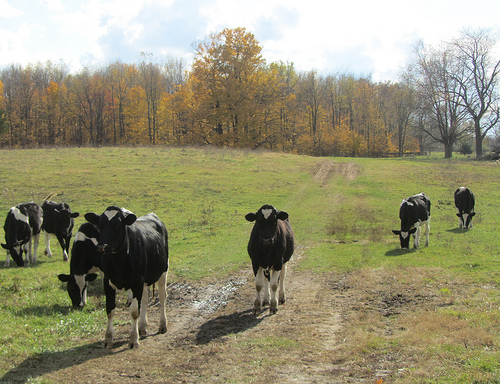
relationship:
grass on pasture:
[2, 146, 497, 381] [0, 21, 497, 381]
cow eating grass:
[391, 191, 431, 251] [2, 146, 497, 381]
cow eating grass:
[0, 194, 44, 274] [2, 146, 497, 381]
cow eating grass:
[52, 209, 136, 315] [2, 146, 497, 381]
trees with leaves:
[4, 28, 409, 163] [0, 28, 452, 153]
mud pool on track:
[168, 284, 230, 324] [301, 153, 393, 383]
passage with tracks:
[215, 135, 395, 380] [294, 148, 381, 200]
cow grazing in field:
[387, 186, 432, 251] [9, 157, 493, 379]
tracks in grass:
[154, 152, 403, 382] [18, 129, 499, 354]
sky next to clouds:
[283, 15, 432, 72] [157, 2, 498, 42]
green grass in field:
[167, 150, 274, 196] [9, 157, 493, 379]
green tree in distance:
[460, 143, 470, 156] [397, 108, 497, 156]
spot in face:
[261, 207, 271, 218] [255, 203, 273, 243]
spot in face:
[104, 207, 117, 218] [97, 207, 123, 257]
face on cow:
[255, 203, 273, 243] [244, 204, 294, 311]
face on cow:
[97, 207, 123, 257] [81, 205, 168, 347]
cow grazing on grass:
[391, 191, 431, 251] [2, 146, 497, 381]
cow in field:
[0, 202, 45, 266] [9, 157, 493, 379]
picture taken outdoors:
[4, 7, 495, 382] [0, 1, 495, 378]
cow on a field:
[391, 191, 431, 251] [0, 157, 500, 384]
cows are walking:
[452, 183, 477, 230] [20, 207, 486, 314]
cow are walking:
[391, 191, 431, 251] [20, 207, 486, 314]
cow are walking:
[243, 203, 294, 315] [20, 207, 486, 314]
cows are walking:
[83, 203, 170, 351] [20, 207, 486, 314]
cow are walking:
[58, 222, 103, 309] [20, 207, 486, 314]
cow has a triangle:
[241, 201, 298, 315] [260, 207, 274, 219]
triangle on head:
[260, 207, 274, 219] [245, 203, 289, 242]